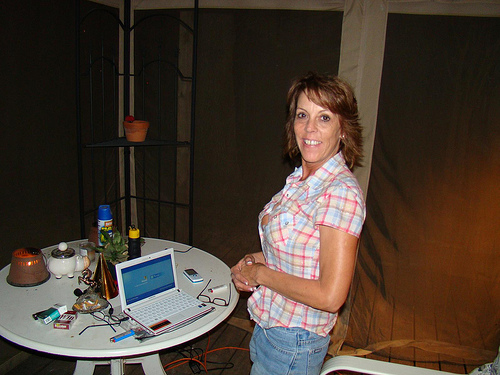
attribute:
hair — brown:
[288, 79, 361, 158]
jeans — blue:
[248, 313, 333, 374]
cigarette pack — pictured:
[53, 309, 78, 331]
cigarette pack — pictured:
[36, 301, 68, 326]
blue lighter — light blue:
[100, 327, 143, 346]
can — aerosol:
[97, 205, 111, 245]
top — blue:
[99, 205, 110, 218]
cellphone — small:
[183, 268, 203, 283]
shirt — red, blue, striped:
[201, 148, 379, 335]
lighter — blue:
[109, 325, 135, 340]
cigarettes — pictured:
[38, 303, 66, 321]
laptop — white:
[113, 246, 214, 336]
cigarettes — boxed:
[33, 302, 63, 324]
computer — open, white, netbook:
[116, 248, 219, 343]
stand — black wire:
[83, 1, 213, 221]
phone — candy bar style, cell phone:
[88, 207, 258, 319]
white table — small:
[1, 217, 236, 372]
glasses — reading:
[198, 261, 264, 338]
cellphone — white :
[177, 259, 209, 291]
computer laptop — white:
[91, 244, 226, 344]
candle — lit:
[26, 259, 31, 265]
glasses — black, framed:
[190, 277, 237, 314]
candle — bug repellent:
[2, 243, 49, 291]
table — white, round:
[0, 232, 245, 372]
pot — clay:
[122, 113, 151, 143]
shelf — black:
[69, 0, 201, 250]